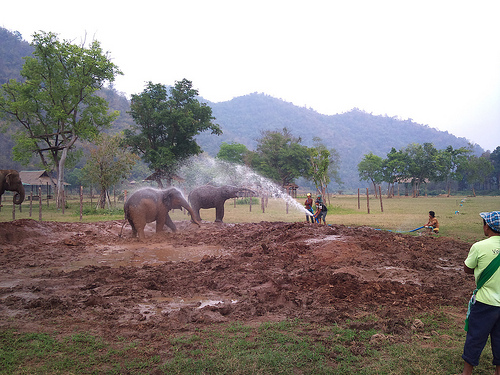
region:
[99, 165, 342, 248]
A man washing off two elephants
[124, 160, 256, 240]
The elephants are getting a bath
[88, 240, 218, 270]
A watery pool of mud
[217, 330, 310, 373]
Sparse patches of grass on the ground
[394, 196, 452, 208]
Short green grass grows in the field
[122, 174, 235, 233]
Two adult elephants in the mud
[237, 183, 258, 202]
The elephant's trunk is raised up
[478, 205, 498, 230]
The man in green has a blue hat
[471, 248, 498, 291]
A green strap on the man's shirt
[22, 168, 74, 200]
A building below the mountains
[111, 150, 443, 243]
dudes happily spraying happy elephants, instead of the other way around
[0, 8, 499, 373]
scene is probably in india, or thereabouts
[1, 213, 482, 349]
a big pile of red brown dirt, made purposefully for elephants+water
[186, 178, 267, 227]
a happy elephant, open mouthed, joyous, taking it all in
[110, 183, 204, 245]
second elephant just beginning to join the festival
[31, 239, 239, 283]
a little lake, almost, of wet muck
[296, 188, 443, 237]
two guys beside them watch the two dudes w/ the blue hose. & the elephants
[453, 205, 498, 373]
guy further back, closer to us, w/ blue hat+green bag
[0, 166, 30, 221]
elephant lining up for the treatment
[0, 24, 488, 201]
mountains in the hazy distance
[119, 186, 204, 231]
The elephant on the left.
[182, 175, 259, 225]
The elephant on the right.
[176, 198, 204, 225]
The trunk of the elephant on the left.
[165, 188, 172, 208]
The ear of the elephant on the left.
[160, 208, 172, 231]
The front legs of the elephant on the left.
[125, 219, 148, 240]
The back legs of the elephant on the left.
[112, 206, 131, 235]
The tail of the elephant on the left.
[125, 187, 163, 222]
The body is the elephant on the left.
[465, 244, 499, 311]
The yellow shirt the man on the right is wearing.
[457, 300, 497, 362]
The blue pants the man is wearing on the right.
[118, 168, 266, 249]
Two elephants getting a bath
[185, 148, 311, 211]
Water being sprayed in the air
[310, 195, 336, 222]
A man washing off two elephants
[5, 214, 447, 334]
A giant mud pit beneath the elephants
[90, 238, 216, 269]
A water filled pool of mud by the elephants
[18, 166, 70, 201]
A small house below the mountains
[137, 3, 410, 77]
The sky is bright and empty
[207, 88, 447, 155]
Tree covered mountains in the background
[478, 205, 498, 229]
A blue hat on the man in green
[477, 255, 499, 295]
A green stripe on the man's shirt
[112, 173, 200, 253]
Large brown elephant in the mud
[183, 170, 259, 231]
Large brown elephant in the mud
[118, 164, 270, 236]
Large brown elephants in the mud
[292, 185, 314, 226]
PErson wearing a hat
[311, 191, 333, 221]
Person wearing a hat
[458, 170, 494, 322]
Person wearing a hat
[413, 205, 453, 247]
Person kneeling down on the ground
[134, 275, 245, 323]
Small mudd puddle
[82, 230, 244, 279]
Large mud puddle